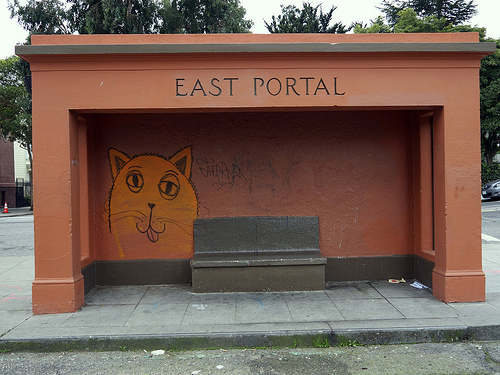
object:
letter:
[222, 75, 238, 98]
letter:
[208, 77, 222, 96]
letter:
[190, 77, 207, 96]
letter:
[251, 75, 264, 96]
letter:
[332, 72, 347, 94]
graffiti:
[255, 144, 352, 194]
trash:
[407, 276, 432, 292]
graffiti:
[184, 147, 250, 194]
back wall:
[81, 107, 417, 283]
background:
[5, 5, 497, 227]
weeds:
[309, 334, 362, 349]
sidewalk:
[0, 240, 499, 353]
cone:
[1, 198, 11, 215]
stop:
[12, 15, 498, 342]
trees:
[434, 17, 499, 201]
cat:
[102, 142, 201, 266]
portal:
[250, 68, 354, 98]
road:
[0, 342, 500, 375]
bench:
[186, 207, 335, 297]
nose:
[481, 182, 496, 199]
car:
[483, 175, 499, 200]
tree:
[0, 53, 36, 217]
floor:
[2, 242, 498, 351]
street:
[2, 322, 497, 373]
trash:
[145, 346, 173, 360]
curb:
[2, 323, 500, 355]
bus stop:
[17, 31, 488, 308]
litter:
[387, 276, 407, 285]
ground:
[0, 198, 499, 373]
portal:
[16, 28, 484, 310]